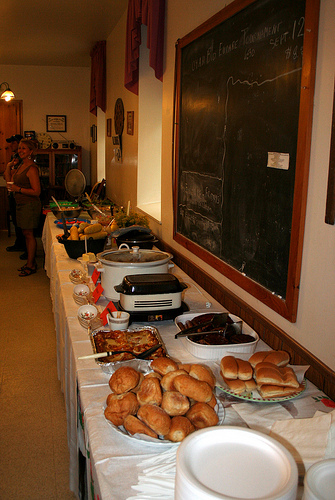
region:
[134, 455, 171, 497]
plastic silverware on a table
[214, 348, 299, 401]
hot roles on a plate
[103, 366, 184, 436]
hot roles on a plate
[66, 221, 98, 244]
corn on the cob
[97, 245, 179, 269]
a crock pot lid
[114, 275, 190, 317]
brown and tan crock pot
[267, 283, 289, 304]
chalk on a chalk holder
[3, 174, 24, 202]
hand holding a cup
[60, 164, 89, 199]
white fan in the corner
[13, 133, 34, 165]
a woman with blonde hair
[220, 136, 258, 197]
part of a blackboard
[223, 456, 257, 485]
inner surface of a plate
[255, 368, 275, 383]
part of a bread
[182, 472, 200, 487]
edge of a plate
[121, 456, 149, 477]
part of a white cloth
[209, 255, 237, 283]
wooden edge of a blackboard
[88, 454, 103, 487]
edge of a table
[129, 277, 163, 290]
part of a black lid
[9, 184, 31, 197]
part of a left arm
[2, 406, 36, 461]
part of the floor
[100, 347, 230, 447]
Bread on white dish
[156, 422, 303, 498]
Stack of white dishes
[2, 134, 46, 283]
Woman close to the table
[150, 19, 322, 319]
Blackboard on wall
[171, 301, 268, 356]
Container with meat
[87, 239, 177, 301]
Pot is white with lid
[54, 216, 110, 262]
French bread on black bowl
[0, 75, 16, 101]
Lamp on left of room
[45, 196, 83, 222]
Bowl of food on table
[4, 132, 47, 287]
Woman wear dress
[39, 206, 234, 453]
Food on a table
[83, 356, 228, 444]
Rolls in a bowl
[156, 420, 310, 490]
A stack of white paper plates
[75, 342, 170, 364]
A serving spoon in a tray of food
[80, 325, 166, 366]
A metal tray of food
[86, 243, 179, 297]
A white crock pot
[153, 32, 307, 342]
A framed blackboard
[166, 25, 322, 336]
A framed blackboard hanging on a wall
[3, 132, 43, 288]
A woman holding a cup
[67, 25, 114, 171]
Red curtains on a window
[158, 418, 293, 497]
a stack of white plates on the table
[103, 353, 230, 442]
rolls of bread in a pile on the table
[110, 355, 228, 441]
rolls are next to the plates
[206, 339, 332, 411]
smaller pile of rolls on the table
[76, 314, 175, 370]
casserole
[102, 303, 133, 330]
a small cup with food in it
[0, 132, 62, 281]
a person is standing next to the table of food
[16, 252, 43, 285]
sandals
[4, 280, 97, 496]
floor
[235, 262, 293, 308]
chalk next to the food